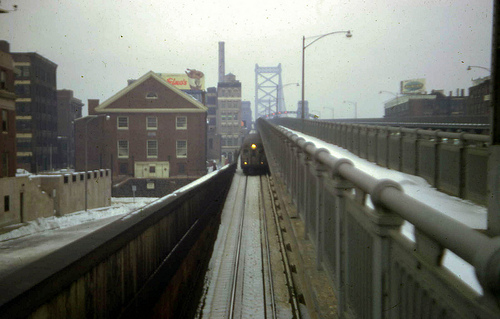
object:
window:
[143, 91, 160, 100]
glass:
[145, 139, 159, 152]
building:
[70, 69, 208, 198]